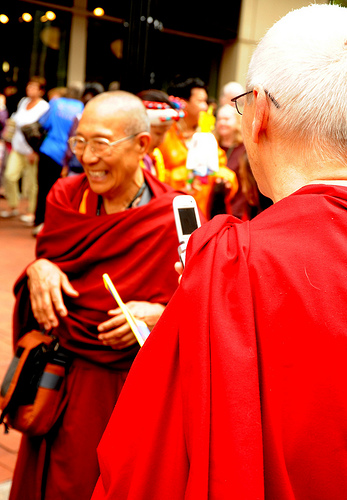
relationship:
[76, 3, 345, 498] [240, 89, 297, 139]
man holds ear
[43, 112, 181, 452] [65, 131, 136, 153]
man wears glasses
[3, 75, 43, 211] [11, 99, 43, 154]
woman wears shirt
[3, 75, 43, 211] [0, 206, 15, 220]
woman wears shoe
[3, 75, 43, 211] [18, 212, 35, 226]
woman wears shoe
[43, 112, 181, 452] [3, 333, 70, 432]
man carries bag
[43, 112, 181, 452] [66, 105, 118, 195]
man has face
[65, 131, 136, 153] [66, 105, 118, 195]
glasses on face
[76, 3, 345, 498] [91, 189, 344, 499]
man wears cloak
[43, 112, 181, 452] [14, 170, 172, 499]
man wears robe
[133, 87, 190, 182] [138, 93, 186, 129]
woman wearing head dress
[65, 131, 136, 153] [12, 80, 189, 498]
glasses on person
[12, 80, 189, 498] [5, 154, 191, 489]
person wearing cape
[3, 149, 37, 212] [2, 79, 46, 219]
pants worn by person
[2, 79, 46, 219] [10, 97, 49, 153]
person wearing tshirt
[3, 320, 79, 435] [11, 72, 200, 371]
bag on side man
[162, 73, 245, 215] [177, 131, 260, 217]
woman wearing clothes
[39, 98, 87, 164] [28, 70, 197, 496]
shirt covering a person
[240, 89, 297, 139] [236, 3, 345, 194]
ear on head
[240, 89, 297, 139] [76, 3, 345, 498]
ear of a man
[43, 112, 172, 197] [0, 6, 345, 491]
man in a crowd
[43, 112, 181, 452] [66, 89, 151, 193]
man with head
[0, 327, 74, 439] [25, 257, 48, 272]
case hanging from wrist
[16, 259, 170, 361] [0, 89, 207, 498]
hands in front of body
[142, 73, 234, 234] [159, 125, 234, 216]
couple in costume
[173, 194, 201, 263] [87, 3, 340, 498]
cell phone held by monk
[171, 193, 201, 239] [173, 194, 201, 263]
top of cell phone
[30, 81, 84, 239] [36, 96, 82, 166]
person wearing shirt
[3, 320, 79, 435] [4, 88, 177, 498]
bag carried by monk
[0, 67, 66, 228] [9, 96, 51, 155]
person wearing t-shirt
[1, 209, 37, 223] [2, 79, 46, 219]
shoes worn by person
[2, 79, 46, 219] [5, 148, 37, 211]
person wearing beige pants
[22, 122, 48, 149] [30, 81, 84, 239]
purse held by person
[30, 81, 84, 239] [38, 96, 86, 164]
person wearing blue shirt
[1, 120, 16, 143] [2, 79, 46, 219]
bag held by person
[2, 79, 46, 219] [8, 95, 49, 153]
person in shirt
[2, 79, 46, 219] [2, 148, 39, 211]
person in pants